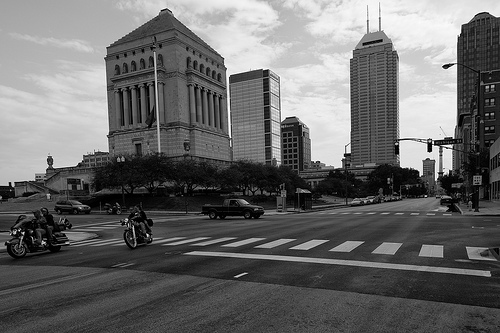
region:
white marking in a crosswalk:
[184, 233, 473, 268]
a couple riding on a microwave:
[8, 202, 81, 258]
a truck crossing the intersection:
[203, 189, 285, 244]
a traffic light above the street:
[383, 123, 452, 155]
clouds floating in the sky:
[243, 2, 280, 48]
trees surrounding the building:
[103, 163, 298, 188]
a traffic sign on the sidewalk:
[463, 166, 485, 197]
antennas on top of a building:
[356, 0, 396, 34]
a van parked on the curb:
[51, 195, 93, 214]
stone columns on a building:
[194, 87, 222, 125]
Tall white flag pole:
[141, 38, 171, 177]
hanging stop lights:
[379, 129, 439, 161]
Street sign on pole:
[430, 131, 470, 157]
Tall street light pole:
[437, 55, 491, 206]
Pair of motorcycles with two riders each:
[5, 203, 158, 267]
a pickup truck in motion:
[196, 197, 276, 226]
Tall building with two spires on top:
[342, 0, 411, 170]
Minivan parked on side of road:
[41, 193, 91, 217]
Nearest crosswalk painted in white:
[87, 228, 496, 278]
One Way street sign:
[466, 165, 492, 205]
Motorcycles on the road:
[1, 177, 178, 259]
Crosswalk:
[195, 221, 487, 302]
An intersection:
[200, 194, 455, 325]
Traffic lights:
[369, 112, 440, 155]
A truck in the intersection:
[199, 183, 312, 275]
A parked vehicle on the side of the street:
[52, 197, 92, 208]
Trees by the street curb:
[91, 162, 241, 193]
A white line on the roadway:
[175, 236, 420, 284]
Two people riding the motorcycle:
[16, 197, 69, 247]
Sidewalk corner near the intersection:
[450, 201, 476, 217]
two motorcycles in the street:
[10, 198, 158, 260]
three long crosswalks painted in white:
[39, 191, 499, 274]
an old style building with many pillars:
[88, 1, 235, 195]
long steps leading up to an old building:
[0, 148, 159, 225]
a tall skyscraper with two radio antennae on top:
[344, 3, 407, 205]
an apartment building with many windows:
[441, 69, 497, 209]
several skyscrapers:
[227, 7, 497, 196]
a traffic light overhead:
[371, 116, 492, 215]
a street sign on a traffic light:
[425, 128, 470, 153]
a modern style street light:
[431, 36, 490, 218]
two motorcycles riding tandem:
[5, 200, 155, 260]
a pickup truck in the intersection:
[198, 195, 404, 270]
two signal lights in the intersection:
[390, 131, 473, 167]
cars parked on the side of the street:
[346, 185, 458, 216]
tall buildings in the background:
[7, 3, 495, 271]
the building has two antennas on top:
[345, 3, 400, 171]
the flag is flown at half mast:
[140, 46, 173, 162]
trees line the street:
[90, 151, 457, 213]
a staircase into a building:
[7, 158, 102, 211]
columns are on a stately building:
[105, 73, 232, 140]